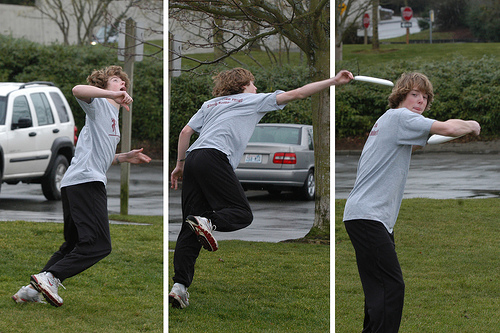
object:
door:
[6, 94, 39, 174]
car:
[0, 81, 79, 200]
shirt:
[185, 90, 285, 171]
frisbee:
[355, 75, 395, 87]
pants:
[343, 219, 409, 333]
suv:
[0, 81, 80, 201]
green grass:
[0, 213, 164, 333]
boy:
[343, 72, 483, 333]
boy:
[169, 67, 353, 309]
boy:
[10, 65, 154, 310]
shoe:
[184, 215, 220, 253]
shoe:
[29, 271, 65, 308]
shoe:
[11, 282, 51, 306]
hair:
[387, 72, 435, 112]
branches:
[0, 0, 136, 61]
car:
[232, 122, 317, 200]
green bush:
[337, 48, 500, 141]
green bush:
[170, 67, 317, 157]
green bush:
[10, 38, 163, 141]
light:
[272, 152, 296, 164]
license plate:
[245, 154, 263, 164]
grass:
[333, 197, 500, 333]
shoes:
[167, 282, 190, 309]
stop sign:
[400, 6, 413, 22]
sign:
[400, 22, 413, 29]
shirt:
[59, 95, 121, 189]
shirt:
[342, 107, 438, 234]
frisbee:
[427, 132, 467, 145]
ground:
[170, 239, 331, 333]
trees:
[169, 0, 332, 245]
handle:
[28, 132, 36, 137]